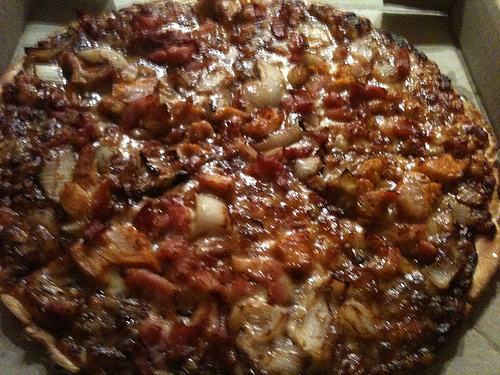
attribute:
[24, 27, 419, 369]
pizza — burnt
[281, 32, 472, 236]
pizza — large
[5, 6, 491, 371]
pizza — triangle, cooked, large, shiny, cut, sliced, baked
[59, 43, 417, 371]
pizza — dark, large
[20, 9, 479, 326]
crust — brown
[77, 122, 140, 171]
onion — large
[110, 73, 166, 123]
ham — large